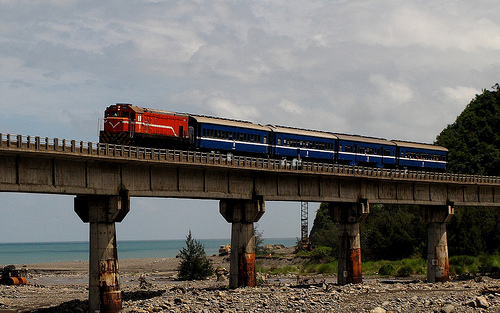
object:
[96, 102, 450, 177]
train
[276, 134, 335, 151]
windows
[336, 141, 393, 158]
windows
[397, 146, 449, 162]
windows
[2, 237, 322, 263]
ocean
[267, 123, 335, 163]
passenger cars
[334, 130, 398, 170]
passenger cars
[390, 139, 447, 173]
passenger cars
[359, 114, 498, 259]
thicket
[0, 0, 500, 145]
clouds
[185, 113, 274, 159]
car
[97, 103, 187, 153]
engine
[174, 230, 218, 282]
tree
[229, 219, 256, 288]
pillar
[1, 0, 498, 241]
grey sky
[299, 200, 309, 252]
tower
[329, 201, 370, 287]
post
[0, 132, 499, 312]
bridge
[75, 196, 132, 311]
post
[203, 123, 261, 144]
windows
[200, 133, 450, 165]
stripe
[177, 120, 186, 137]
door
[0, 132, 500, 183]
railroad